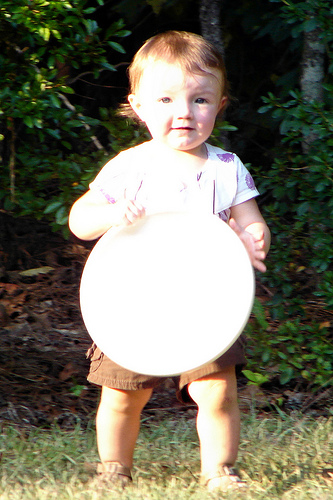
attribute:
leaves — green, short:
[271, 117, 326, 297]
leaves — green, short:
[0, 0, 68, 242]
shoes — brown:
[83, 459, 148, 496]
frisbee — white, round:
[68, 198, 264, 386]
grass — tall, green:
[259, 129, 321, 304]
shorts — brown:
[59, 324, 262, 385]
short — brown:
[48, 302, 248, 403]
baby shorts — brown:
[86, 70, 272, 415]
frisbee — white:
[78, 210, 254, 376]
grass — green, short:
[12, 431, 73, 492]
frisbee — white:
[96, 200, 285, 398]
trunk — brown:
[302, 12, 321, 143]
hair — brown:
[120, 20, 240, 82]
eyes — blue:
[153, 86, 198, 113]